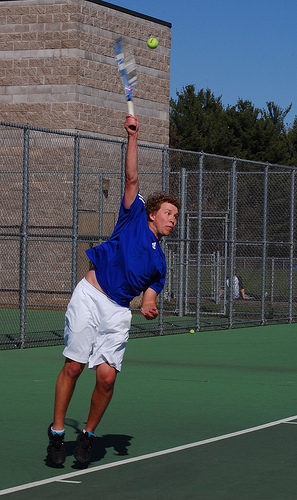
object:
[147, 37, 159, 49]
tennis ball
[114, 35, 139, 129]
racket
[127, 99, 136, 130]
handle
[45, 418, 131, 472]
shadow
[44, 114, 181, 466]
man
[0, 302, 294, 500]
court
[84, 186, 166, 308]
shirt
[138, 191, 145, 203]
stripes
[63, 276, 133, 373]
shorts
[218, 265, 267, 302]
man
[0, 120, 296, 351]
fence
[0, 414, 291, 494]
line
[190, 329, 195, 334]
tennis ball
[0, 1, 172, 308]
building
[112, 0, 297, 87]
sky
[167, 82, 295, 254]
trees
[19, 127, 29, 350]
pole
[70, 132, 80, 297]
pole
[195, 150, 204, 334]
pole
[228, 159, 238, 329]
pole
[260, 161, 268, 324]
pole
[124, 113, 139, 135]
right hand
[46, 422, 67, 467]
shoes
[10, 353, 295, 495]
ground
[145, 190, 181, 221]
hair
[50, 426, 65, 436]
socks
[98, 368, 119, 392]
knee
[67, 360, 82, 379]
knee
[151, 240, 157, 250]
logo